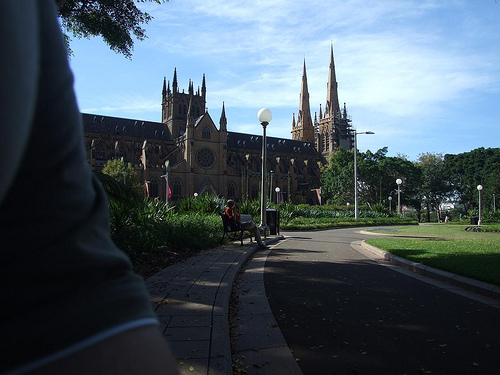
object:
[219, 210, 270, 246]
bench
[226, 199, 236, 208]
head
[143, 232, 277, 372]
curb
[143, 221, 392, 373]
sidewalk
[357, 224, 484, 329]
curb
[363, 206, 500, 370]
area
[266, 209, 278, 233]
can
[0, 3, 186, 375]
person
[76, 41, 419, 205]
building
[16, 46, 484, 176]
distance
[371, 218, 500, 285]
grass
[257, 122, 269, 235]
pole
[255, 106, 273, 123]
lamp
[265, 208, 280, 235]
bin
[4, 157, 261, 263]
bushes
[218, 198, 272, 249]
man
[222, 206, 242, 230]
shirt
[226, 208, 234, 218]
arm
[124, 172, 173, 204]
flags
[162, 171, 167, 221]
pole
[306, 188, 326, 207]
flag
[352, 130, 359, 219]
pole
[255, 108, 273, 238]
lamp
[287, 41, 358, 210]
towers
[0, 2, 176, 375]
shirt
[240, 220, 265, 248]
legs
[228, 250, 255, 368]
leaves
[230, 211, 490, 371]
pavement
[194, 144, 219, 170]
design inset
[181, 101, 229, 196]
abbey